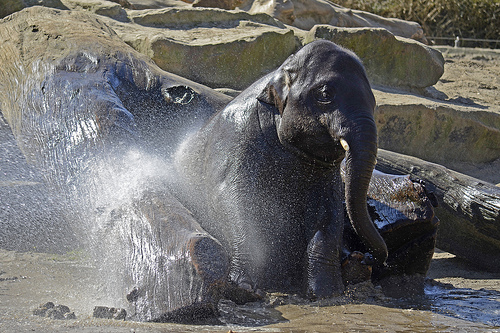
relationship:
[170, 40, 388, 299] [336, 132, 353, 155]
elephant has a tusk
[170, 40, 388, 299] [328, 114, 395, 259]
elephant has trunk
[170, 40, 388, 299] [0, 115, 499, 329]
elephant sitting in water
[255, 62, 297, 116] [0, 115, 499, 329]
ear covered in water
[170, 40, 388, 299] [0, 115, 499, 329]
elephant covered in water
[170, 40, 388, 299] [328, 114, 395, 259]
elephant has a trunk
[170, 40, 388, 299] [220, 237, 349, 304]
elephant has feet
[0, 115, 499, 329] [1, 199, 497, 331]
water standing on ground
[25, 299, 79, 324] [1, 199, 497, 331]
elephant droppings on ground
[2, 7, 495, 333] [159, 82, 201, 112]
tree trunk has a knot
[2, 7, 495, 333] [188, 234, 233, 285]
tree trunk has a knot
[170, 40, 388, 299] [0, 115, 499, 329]
elephant sprayed with water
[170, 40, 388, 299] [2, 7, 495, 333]
elephant sitting inside of tree trunk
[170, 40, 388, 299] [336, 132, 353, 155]
elephant has tusk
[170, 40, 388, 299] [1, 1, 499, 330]
elephant in a zoo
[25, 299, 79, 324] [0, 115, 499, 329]
elephant droppings lying in water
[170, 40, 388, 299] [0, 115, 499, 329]
elephant enjoys water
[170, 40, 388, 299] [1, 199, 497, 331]
elephant sitting on ground